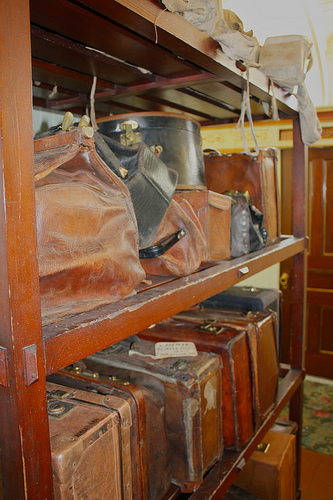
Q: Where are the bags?
A: The shelf.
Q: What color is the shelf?
A: Brown.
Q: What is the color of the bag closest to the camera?
A: Brown.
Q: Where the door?
A: The background.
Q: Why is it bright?
A: Indoor lighting.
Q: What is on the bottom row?
A: Suitcases.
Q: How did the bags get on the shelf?
A: They were put there.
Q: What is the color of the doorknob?
A: Gold.